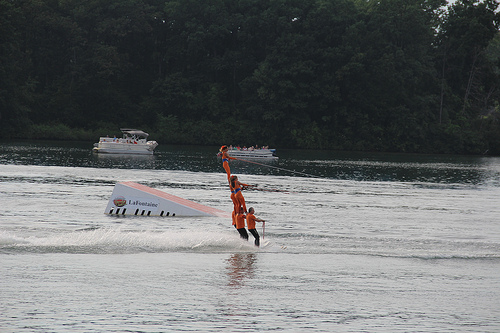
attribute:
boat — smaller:
[215, 136, 279, 161]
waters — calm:
[38, 244, 488, 327]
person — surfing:
[247, 210, 267, 246]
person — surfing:
[235, 210, 249, 241]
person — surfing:
[231, 179, 252, 205]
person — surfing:
[223, 181, 239, 212]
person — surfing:
[216, 143, 232, 179]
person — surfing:
[231, 174, 257, 213]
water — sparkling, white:
[3, 144, 495, 328]